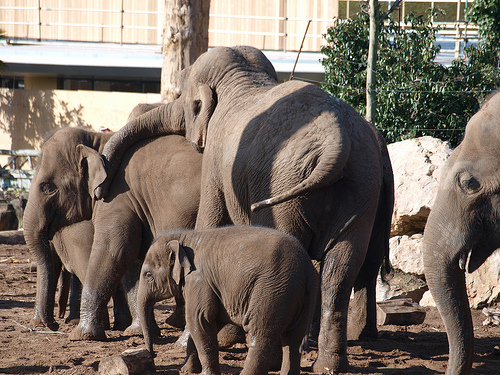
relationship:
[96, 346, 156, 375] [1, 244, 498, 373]
rock on ground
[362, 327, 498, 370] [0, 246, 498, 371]
shadows on dirt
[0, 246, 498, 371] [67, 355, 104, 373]
dirt in prints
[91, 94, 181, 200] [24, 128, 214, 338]
elephant trunk on another elephant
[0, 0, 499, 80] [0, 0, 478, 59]
balcony with a fence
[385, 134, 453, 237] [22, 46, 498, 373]
boulder next to animals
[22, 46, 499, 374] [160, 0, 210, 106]
animals by a pole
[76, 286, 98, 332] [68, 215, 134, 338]
powder on leg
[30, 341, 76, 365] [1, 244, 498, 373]
dirt on ground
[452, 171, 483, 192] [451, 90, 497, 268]
eye on side face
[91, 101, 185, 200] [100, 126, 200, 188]
elephant trunk laying on elephant's back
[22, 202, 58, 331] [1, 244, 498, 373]
elephant trunk hanging down ground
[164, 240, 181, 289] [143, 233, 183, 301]
ear on side head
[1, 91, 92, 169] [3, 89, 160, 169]
shadows on wall